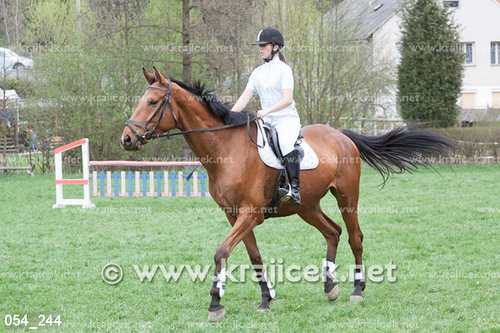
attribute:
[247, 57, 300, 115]
shirt — white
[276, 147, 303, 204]
boot — black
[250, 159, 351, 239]
boots — leather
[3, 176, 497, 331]
grass — green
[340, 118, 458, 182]
tail — black